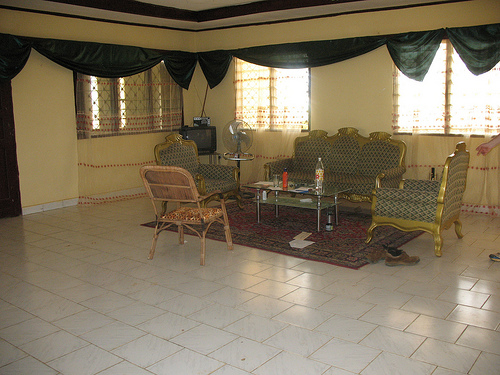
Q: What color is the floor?
A: White.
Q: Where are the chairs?
A: In the living room.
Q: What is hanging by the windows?
A: Curtains.